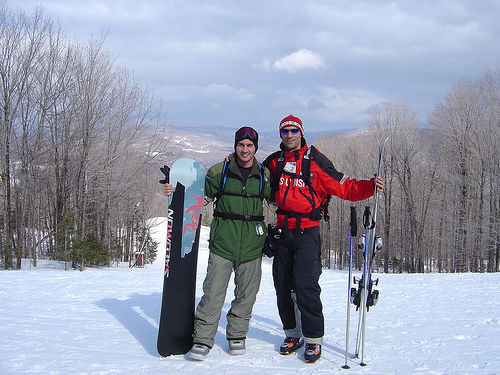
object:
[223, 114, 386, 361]
man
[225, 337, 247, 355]
boot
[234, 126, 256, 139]
ski goggles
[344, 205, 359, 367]
sports equipment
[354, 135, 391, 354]
skis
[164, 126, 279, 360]
man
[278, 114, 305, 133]
cap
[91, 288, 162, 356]
shadow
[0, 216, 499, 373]
snow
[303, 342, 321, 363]
ski boots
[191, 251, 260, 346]
trousers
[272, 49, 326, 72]
clouds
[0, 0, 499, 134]
sky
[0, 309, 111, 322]
ski trail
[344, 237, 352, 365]
pole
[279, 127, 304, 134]
sunglasses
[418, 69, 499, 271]
trees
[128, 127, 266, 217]
mountains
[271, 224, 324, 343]
pants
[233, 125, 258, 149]
hat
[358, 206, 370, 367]
skis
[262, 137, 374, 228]
jacket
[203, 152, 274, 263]
jacket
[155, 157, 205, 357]
snowboard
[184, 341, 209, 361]
boot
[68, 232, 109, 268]
bush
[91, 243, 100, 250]
leaves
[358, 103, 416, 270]
tree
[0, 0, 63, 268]
tree